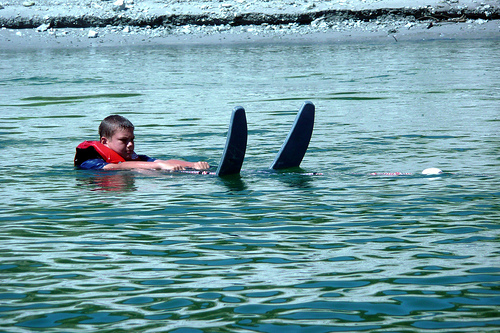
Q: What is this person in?
A: Water.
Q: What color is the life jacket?
A: Red.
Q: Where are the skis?
A: In front of the boy.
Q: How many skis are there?
A: Two.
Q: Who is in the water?
A: The boy with skis.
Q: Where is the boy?
A: In the water.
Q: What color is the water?
A: Blue.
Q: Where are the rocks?
A: On the shore line.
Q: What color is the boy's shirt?
A: Blue.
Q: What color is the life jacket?
A: Red.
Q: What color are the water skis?
A: Blue.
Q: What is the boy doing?
A: Water skiing.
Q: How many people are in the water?
A: One.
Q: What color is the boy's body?
A: Pink.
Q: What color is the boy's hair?
A: Dark Brown.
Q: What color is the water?
A: Blue.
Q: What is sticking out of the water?
A: Water skis.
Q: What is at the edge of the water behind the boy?
A: Sand and rocks.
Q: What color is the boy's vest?
A: Red.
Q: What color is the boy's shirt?
A: Blue.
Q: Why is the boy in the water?
A: He is water skiing.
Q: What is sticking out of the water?
A: Water skis.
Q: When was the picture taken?
A: Daytime.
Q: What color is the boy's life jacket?
A: Red.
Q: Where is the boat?
A: Ahead of the boy.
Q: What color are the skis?
A: Blue.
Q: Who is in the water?
A: The boy.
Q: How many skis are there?
A: Two.